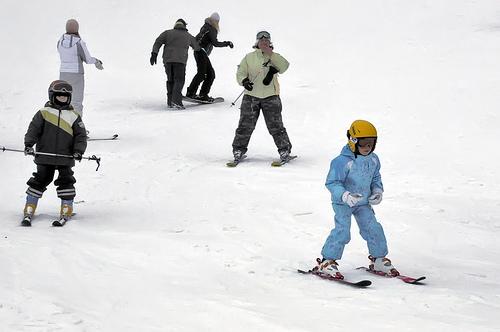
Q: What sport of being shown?
A: Skiing.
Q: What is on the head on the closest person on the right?
A: Helmet.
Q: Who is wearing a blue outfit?
A: Person on the right.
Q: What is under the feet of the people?
A: Skis.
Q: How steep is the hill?
A: Beginners' slope, not steep.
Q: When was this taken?
A: During the winter.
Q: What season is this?
A: Winter.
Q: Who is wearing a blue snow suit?
A: A girl.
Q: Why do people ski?
A: Recreation and exercise.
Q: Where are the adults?
A: Behind the kids.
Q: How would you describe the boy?
A: Young.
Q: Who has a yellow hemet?
A: The girl.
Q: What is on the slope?
A: Snow.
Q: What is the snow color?
A: White.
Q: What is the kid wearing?
A: Skis.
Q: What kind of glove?
A: Left.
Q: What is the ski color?
A: Red.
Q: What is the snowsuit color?
A: Blue.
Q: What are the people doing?
A: Skiing.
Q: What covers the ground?
A: Snow.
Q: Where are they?
A: On snow.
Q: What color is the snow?
A: White.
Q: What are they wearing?
A: Jackets.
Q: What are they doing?
A: Skiing.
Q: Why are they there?
A: To ski.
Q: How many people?
A: 6.